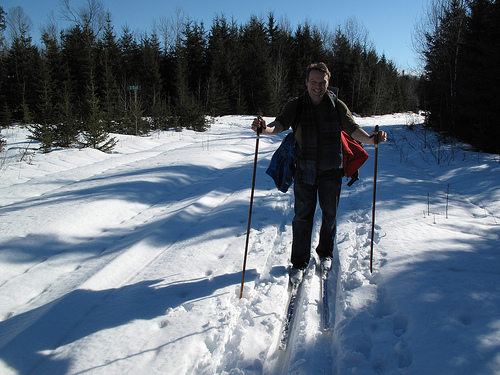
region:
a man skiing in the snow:
[198, 17, 468, 362]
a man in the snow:
[173, 29, 449, 316]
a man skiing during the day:
[208, 48, 467, 341]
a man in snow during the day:
[153, 11, 456, 324]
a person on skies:
[176, 13, 497, 353]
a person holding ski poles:
[194, 32, 464, 344]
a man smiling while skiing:
[211, 18, 480, 319]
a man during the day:
[164, 22, 436, 322]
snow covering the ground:
[102, 6, 469, 308]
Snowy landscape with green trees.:
[2, 8, 209, 325]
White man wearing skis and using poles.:
[223, 31, 433, 352]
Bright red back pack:
[340, 134, 373, 189]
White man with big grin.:
[294, 57, 354, 107]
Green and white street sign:
[109, 73, 157, 117]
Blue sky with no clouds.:
[370, 10, 421, 47]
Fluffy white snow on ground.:
[68, 220, 198, 310]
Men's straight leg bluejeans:
[282, 163, 347, 286]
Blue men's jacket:
[265, 133, 307, 192]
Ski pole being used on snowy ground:
[227, 111, 270, 308]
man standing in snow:
[258, 37, 400, 322]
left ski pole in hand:
[366, 111, 386, 296]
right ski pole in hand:
[245, 95, 259, 330]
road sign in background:
[123, 76, 148, 123]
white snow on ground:
[112, 237, 214, 319]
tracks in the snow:
[97, 209, 135, 250]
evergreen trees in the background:
[161, 2, 224, 115]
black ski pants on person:
[286, 155, 341, 286]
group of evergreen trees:
[423, 9, 482, 171]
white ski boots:
[288, 255, 338, 280]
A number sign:
[121, 82, 147, 99]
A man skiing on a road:
[235, 53, 387, 344]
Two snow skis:
[280, 261, 336, 354]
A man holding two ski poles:
[235, 61, 387, 316]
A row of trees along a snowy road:
[5, 30, 272, 143]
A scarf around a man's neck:
[292, 67, 348, 189]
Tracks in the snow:
[206, 304, 436, 373]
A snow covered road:
[12, 142, 498, 372]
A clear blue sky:
[77, 1, 411, 43]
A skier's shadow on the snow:
[2, 267, 264, 373]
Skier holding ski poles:
[230, 53, 430, 318]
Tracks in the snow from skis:
[197, 307, 407, 367]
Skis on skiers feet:
[285, 251, 336, 347]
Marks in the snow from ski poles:
[340, 275, 411, 370]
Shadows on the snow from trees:
[12, 165, 223, 270]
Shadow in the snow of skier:
[0, 266, 270, 371]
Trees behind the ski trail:
[7, 5, 259, 105]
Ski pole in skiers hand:
[225, 110, 265, 297]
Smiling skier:
[281, 52, 346, 107]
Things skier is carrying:
[261, 125, 371, 198]